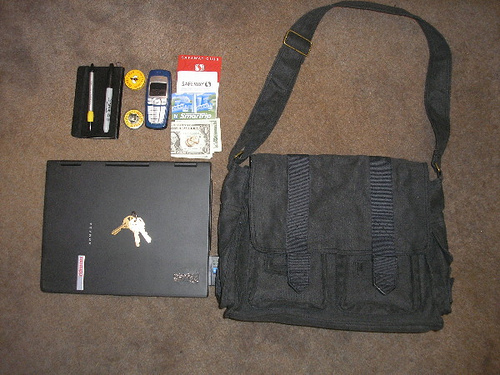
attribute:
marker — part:
[102, 62, 114, 133]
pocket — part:
[253, 251, 328, 310]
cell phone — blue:
[140, 63, 175, 133]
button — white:
[140, 98, 172, 124]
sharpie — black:
[98, 55, 120, 134]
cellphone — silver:
[141, 66, 173, 138]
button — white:
[148, 99, 163, 124]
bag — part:
[216, 12, 463, 335]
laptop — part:
[21, 140, 228, 312]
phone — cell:
[141, 72, 167, 132]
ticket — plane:
[172, 50, 222, 118]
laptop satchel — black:
[179, 132, 458, 342]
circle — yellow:
[123, 69, 145, 89]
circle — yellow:
[123, 109, 143, 129]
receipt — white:
[176, 69, 228, 115]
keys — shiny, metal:
[122, 217, 155, 251]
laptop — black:
[37, 157, 211, 299]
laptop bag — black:
[216, 2, 454, 337]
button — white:
[158, 110, 166, 119]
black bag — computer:
[213, 1, 456, 336]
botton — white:
[149, 117, 154, 121]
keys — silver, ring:
[127, 217, 159, 249]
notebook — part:
[71, 65, 124, 137]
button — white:
[152, 111, 162, 117]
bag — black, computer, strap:
[189, 133, 456, 303]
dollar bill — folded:
[166, 120, 215, 162]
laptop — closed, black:
[163, 142, 218, 268]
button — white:
[145, 94, 156, 105]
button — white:
[145, 98, 153, 110]